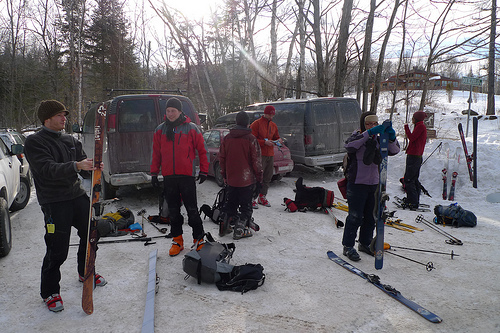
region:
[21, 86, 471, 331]
The skiers stand together.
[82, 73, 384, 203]
Vehicles are behind the skiers.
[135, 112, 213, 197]
The skier's jacket is red.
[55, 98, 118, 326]
The skier holds his ski.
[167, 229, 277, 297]
Bags are on the ground.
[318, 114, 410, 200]
The skier's jacket is purple.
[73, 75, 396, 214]
Two vans are behind the skiers.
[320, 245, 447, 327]
The ski is blue.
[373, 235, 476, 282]
Ski poles are on the ground.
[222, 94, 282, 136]
The skiers wear hats.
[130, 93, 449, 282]
people standing on snow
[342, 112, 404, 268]
person holding ski vertically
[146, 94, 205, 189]
man in red jacket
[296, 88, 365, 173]
back of parked van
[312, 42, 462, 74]
tree braches with no leaves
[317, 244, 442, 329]
blue ski on snow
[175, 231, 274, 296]
bags laying on ground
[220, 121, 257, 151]
hood on person's jacket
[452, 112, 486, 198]
skis stuck in snow bank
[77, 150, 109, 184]
two hands on ski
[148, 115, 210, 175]
Red and grey jacket worn by a man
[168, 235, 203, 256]
Orange ski boots worn by a man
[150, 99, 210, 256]
Man wearing red jacket and black pants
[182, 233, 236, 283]
Grey and black backpack laying on the ground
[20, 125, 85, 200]
Black jacket worn by a man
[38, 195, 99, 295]
Black pants worn by a man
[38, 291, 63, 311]
Grey and red ski boot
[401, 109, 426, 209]
Person wearing red jacket and black pants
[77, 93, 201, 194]
Red and black colored van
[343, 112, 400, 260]
Person wearing a purple and black jacket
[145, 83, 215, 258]
a man in a red jacket.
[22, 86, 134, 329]
a kid holding a snowboard.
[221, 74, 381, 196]
a parked van.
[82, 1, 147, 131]
a large green tree.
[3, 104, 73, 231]
a parked white vehicle.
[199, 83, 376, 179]
a shiney parked van.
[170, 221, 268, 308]
a pile of bags on the ground.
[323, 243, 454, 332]
a ski laying on the ground.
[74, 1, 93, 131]
a tall leafless tree.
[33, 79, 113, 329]
A man holding ski equipment.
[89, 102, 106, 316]
brown and orange ski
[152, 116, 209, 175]
red and grey winter coat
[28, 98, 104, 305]
man wearing brown hat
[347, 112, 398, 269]
man holding blue ski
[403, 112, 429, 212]
man wearing red jacket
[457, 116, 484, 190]
skis sitting in snow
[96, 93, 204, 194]
red van parked in lot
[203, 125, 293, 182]
red car parked in lot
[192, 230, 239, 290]
grey back packon ground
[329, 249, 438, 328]
blue ski on ground